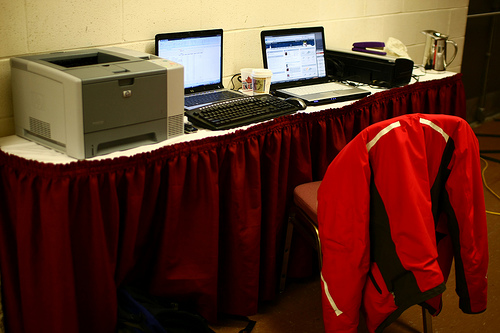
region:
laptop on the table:
[264, 27, 351, 104]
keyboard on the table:
[200, 98, 296, 123]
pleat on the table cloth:
[81, 174, 109, 330]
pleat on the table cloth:
[138, 161, 168, 326]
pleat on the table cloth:
[173, 154, 198, 331]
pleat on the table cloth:
[196, 150, 221, 324]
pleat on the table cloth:
[227, 153, 249, 330]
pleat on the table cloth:
[47, 173, 72, 324]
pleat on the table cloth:
[272, 125, 282, 306]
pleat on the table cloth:
[185, 158, 215, 327]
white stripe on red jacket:
[302, 258, 347, 318]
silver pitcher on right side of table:
[413, 11, 450, 91]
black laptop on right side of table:
[258, 36, 356, 126]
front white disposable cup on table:
[254, 67, 276, 91]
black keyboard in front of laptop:
[191, 98, 307, 136]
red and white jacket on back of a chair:
[308, 138, 494, 285]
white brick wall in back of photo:
[66, 3, 121, 33]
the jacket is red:
[321, 103, 493, 331]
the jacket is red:
[304, 108, 476, 325]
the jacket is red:
[299, 116, 479, 311]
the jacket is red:
[285, 122, 482, 330]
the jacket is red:
[288, 116, 475, 328]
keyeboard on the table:
[190, 85, 322, 162]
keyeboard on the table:
[173, 65, 326, 175]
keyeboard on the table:
[182, 85, 302, 165]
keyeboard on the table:
[177, 85, 328, 168]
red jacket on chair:
[308, 95, 491, 327]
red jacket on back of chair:
[301, 72, 488, 332]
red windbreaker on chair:
[308, 110, 498, 331]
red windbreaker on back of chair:
[317, 102, 494, 330]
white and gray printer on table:
[19, 40, 188, 162]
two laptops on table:
[155, 18, 381, 133]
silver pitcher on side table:
[415, 19, 455, 86]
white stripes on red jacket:
[311, 96, 481, 331]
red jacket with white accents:
[313, 100, 486, 331]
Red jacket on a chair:
[295, 108, 495, 329]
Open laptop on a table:
[257, 22, 372, 104]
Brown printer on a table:
[8, 43, 188, 164]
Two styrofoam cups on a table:
[236, 65, 273, 99]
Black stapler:
[348, 38, 389, 58]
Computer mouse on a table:
[181, 120, 197, 138]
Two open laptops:
[151, 22, 376, 130]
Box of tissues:
[375, 33, 410, 66]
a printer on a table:
[8, 45, 185, 155]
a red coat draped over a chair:
[317, 115, 490, 332]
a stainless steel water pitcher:
[418, 21, 458, 72]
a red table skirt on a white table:
[0, 67, 466, 332]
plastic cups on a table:
[238, 65, 273, 93]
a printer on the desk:
[15, 47, 185, 158]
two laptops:
[160, 32, 367, 117]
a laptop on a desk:
[161, 31, 276, 131]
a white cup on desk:
[250, 65, 265, 90]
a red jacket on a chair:
[325, 120, 480, 325]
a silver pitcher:
[425, 25, 450, 65]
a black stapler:
[351, 37, 383, 52]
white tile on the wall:
[5, 5, 281, 30]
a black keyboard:
[195, 90, 287, 126]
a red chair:
[280, 155, 453, 321]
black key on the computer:
[192, 110, 200, 115]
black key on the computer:
[196, 111, 201, 116]